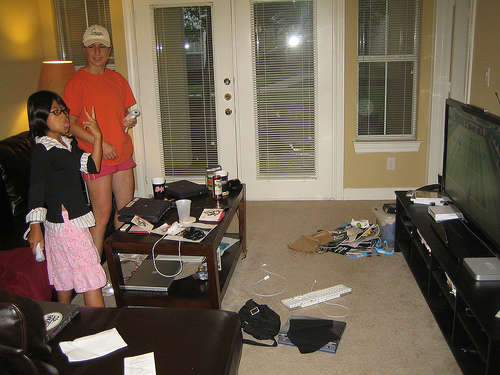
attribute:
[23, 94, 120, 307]
girl — looking, posing, blowing, playing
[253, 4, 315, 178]
door — white, frenc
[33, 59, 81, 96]
lamp — on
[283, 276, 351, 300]
keyboard — white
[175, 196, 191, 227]
cup — plastic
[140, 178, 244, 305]
table — brown, wooden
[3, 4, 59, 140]
wall — tan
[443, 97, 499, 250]
tv — large, flatscreen, on, widescreen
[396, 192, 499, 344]
table — brown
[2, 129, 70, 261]
couch — dark, brown, leather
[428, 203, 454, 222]
game system — wii, white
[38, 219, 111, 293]
skirt — pink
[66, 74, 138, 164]
shirt — orange, black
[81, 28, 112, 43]
hat — tan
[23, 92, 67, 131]
hair — straight, dark